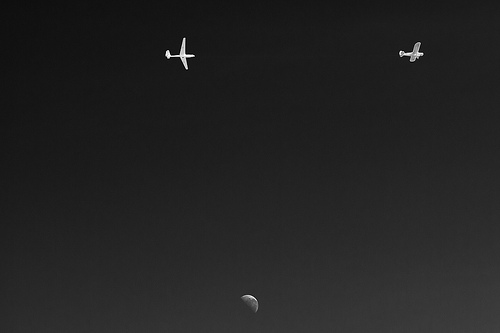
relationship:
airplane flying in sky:
[165, 38, 196, 70] [7, 6, 482, 323]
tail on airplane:
[165, 49, 172, 59] [165, 38, 196, 70]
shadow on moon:
[247, 296, 257, 303] [234, 293, 258, 315]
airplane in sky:
[165, 38, 196, 70] [7, 6, 482, 323]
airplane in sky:
[399, 41, 424, 62] [7, 6, 482, 323]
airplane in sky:
[162, 38, 196, 75] [7, 6, 482, 323]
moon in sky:
[240, 295, 259, 314] [7, 6, 482, 323]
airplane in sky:
[165, 38, 196, 70] [22, 20, 454, 322]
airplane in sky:
[399, 41, 424, 62] [22, 20, 454, 322]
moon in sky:
[240, 295, 259, 314] [22, 20, 454, 322]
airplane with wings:
[165, 38, 196, 70] [177, 31, 188, 73]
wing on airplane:
[180, 57, 189, 71] [165, 38, 196, 70]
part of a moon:
[239, 304, 252, 313] [238, 290, 263, 320]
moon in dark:
[240, 295, 259, 314] [30, 23, 448, 322]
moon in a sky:
[240, 295, 259, 314] [22, 20, 454, 322]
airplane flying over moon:
[165, 38, 196, 70] [235, 285, 268, 316]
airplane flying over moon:
[399, 41, 424, 62] [235, 285, 268, 316]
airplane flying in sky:
[399, 41, 424, 62] [7, 6, 482, 323]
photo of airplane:
[12, 22, 453, 320] [165, 38, 196, 70]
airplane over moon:
[165, 38, 196, 70] [217, 290, 278, 312]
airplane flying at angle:
[399, 41, 424, 62] [398, 37, 432, 65]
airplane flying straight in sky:
[165, 38, 196, 70] [22, 20, 454, 322]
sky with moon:
[22, 20, 454, 322] [235, 279, 275, 314]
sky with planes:
[22, 20, 454, 322] [393, 36, 427, 67]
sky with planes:
[22, 20, 454, 322] [160, 34, 201, 74]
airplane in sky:
[165, 38, 196, 70] [89, 128, 373, 258]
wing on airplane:
[178, 37, 187, 52] [165, 38, 196, 70]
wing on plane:
[180, 55, 190, 68] [164, 34, 197, 70]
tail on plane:
[165, 49, 172, 59] [165, 37, 196, 71]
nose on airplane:
[186, 53, 196, 57] [165, 38, 196, 70]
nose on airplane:
[418, 50, 426, 56] [398, 40, 426, 63]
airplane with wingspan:
[165, 38, 196, 70] [178, 37, 189, 70]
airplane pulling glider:
[399, 41, 424, 62] [167, 36, 197, 71]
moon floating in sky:
[240, 293, 260, 313] [7, 6, 482, 323]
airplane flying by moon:
[165, 38, 196, 70] [242, 291, 261, 312]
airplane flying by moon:
[399, 41, 424, 62] [239, 292, 259, 316]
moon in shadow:
[240, 295, 259, 314] [240, 298, 254, 315]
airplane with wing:
[165, 38, 196, 70] [179, 33, 188, 53]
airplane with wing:
[165, 38, 196, 70] [180, 57, 190, 70]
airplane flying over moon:
[165, 38, 196, 70] [238, 292, 258, 313]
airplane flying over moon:
[399, 40, 424, 62] [238, 292, 258, 313]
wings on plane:
[406, 40, 422, 61] [392, 38, 424, 62]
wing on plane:
[178, 37, 187, 54] [162, 44, 202, 74]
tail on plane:
[164, 44, 177, 65] [162, 38, 196, 70]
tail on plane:
[398, 44, 404, 62] [395, 32, 425, 62]